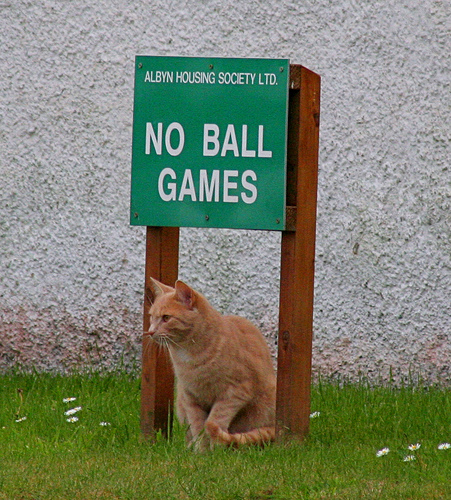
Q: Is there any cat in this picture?
A: Yes, there is a cat.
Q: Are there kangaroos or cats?
A: Yes, there is a cat.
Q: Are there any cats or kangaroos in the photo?
A: Yes, there is a cat.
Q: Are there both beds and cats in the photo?
A: No, there is a cat but no beds.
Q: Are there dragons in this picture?
A: No, there are no dragons.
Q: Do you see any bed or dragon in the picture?
A: No, there are no dragons or beds.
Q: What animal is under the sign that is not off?
A: The cat is under the sign.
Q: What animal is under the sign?
A: The cat is under the sign.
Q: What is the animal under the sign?
A: The animal is a cat.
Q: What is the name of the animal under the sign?
A: The animal is a cat.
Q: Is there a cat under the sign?
A: Yes, there is a cat under the sign.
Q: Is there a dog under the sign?
A: No, there is a cat under the sign.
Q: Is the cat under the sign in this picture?
A: Yes, the cat is under the sign.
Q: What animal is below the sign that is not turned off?
A: The animal is a cat.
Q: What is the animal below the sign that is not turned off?
A: The animal is a cat.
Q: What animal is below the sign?
A: The animal is a cat.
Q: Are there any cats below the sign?
A: Yes, there is a cat below the sign.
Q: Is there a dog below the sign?
A: No, there is a cat below the sign.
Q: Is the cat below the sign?
A: Yes, the cat is below the sign.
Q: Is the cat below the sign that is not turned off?
A: Yes, the cat is below the sign.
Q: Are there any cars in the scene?
A: No, there are no cars.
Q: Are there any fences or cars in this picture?
A: No, there are no cars or fences.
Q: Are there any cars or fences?
A: No, there are no cars or fences.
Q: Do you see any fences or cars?
A: No, there are no cars or fences.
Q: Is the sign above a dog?
A: No, the sign is above the cat.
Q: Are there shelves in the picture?
A: No, there are no shelves.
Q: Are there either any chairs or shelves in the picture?
A: No, there are no shelves or chairs.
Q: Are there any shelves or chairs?
A: No, there are no shelves or chairs.